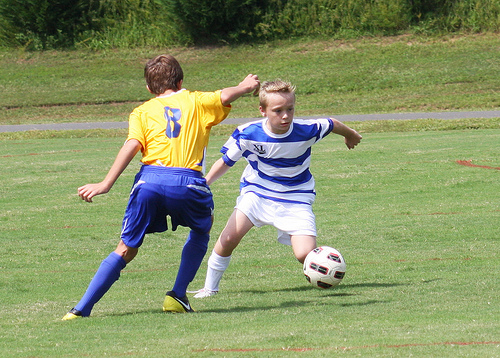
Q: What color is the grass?
A: Green.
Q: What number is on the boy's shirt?
A: 8.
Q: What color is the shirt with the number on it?
A: Yellow.